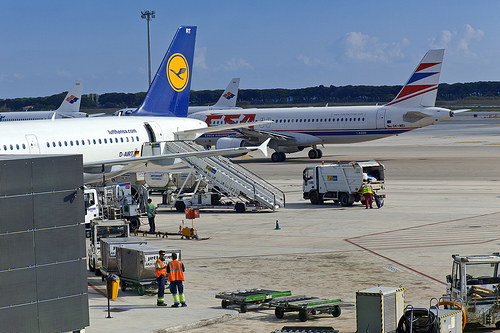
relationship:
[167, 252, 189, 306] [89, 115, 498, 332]
person on tarmac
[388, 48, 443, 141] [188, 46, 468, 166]
tail on plane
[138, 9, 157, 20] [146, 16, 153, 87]
light on pole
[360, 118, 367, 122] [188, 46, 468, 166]
window on plane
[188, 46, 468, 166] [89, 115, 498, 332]
plane on tarmac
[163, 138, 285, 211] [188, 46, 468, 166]
steps by plane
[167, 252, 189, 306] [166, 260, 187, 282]
person in top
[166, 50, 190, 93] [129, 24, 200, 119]
logo on fin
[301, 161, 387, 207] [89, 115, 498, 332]
truck on tarmac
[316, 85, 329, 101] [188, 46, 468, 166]
tree behind plane